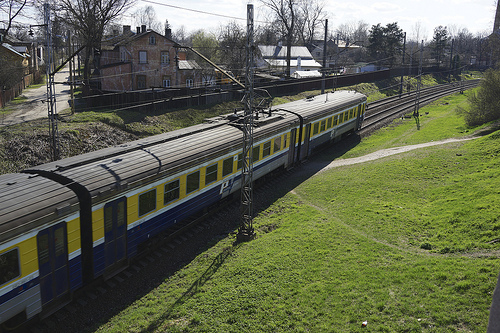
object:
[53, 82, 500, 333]
meadow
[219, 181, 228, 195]
letter "p"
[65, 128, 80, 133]
grass patch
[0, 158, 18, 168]
grass patch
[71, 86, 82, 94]
grass patch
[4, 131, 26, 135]
grass patch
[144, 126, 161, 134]
grass patch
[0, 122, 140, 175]
rocky slope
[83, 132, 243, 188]
stripe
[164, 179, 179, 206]
windows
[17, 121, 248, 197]
roof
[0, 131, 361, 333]
shadow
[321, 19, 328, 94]
pole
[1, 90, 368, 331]
train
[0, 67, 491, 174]
hill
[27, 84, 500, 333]
hill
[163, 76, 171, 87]
windows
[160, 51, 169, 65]
windows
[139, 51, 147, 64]
windows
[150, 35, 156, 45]
windows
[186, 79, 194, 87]
windows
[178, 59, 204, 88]
house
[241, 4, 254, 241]
pole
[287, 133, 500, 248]
grass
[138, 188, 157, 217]
window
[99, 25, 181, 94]
house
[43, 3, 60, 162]
poles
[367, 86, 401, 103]
grass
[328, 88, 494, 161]
grass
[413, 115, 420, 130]
shadows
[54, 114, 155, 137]
shadows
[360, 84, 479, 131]
tracks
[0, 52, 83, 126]
road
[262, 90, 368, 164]
car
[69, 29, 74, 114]
pole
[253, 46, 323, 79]
house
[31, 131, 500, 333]
grass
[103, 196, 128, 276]
door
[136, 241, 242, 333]
shadow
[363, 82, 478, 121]
tracks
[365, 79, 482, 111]
tracks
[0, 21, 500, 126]
city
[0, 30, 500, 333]
ground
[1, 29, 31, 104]
houses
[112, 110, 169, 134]
slope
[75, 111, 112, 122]
grass